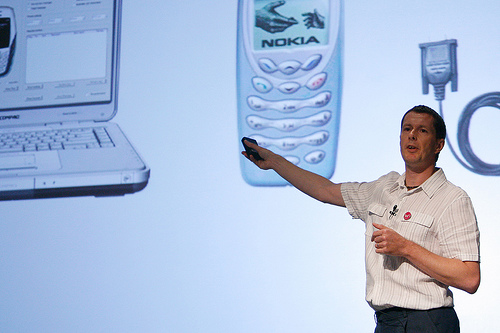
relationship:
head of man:
[392, 105, 452, 173] [244, 99, 487, 330]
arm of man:
[239, 134, 353, 216] [244, 99, 487, 330]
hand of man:
[369, 222, 405, 257] [244, 99, 487, 330]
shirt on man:
[338, 164, 481, 310] [244, 99, 487, 330]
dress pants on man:
[372, 301, 462, 331] [244, 99, 487, 330]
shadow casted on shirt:
[380, 253, 410, 271] [338, 164, 481, 310]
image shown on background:
[2, 1, 483, 330] [1, 1, 483, 329]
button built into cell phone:
[251, 74, 271, 93] [232, 0, 345, 190]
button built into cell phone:
[246, 93, 270, 112] [232, 0, 345, 190]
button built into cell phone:
[275, 80, 300, 94] [232, 0, 345, 190]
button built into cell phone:
[306, 110, 332, 126] [232, 0, 345, 190]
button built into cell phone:
[303, 129, 330, 147] [232, 0, 345, 190]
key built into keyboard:
[50, 140, 62, 146] [2, 123, 116, 153]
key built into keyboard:
[23, 146, 38, 152] [2, 123, 116, 153]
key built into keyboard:
[25, 136, 39, 142] [2, 123, 116, 153]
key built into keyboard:
[66, 127, 81, 133] [2, 123, 116, 153]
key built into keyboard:
[2, 137, 16, 144] [2, 123, 116, 153]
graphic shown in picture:
[0, 0, 157, 209] [2, 2, 484, 328]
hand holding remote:
[240, 137, 273, 172] [241, 135, 261, 159]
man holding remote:
[244, 99, 487, 330] [241, 135, 261, 159]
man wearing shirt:
[244, 99, 487, 330] [338, 164, 481, 310]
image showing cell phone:
[2, 1, 483, 330] [232, 0, 345, 190]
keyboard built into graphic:
[2, 123, 116, 153] [0, 0, 157, 209]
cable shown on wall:
[435, 89, 484, 179] [0, 5, 482, 331]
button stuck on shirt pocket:
[402, 210, 411, 218] [396, 208, 434, 241]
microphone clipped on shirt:
[386, 203, 398, 221] [338, 164, 481, 310]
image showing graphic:
[2, 1, 483, 330] [0, 0, 157, 209]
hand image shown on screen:
[254, 1, 298, 32] [252, 1, 332, 49]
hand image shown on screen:
[298, 7, 326, 30] [252, 1, 332, 49]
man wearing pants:
[244, 99, 487, 330] [371, 304, 462, 331]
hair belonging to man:
[398, 103, 448, 165] [244, 99, 487, 330]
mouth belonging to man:
[400, 140, 420, 154] [244, 99, 487, 330]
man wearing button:
[244, 99, 487, 330] [402, 210, 411, 218]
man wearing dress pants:
[244, 99, 487, 330] [372, 301, 462, 331]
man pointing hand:
[244, 99, 487, 330] [240, 137, 273, 172]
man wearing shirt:
[244, 99, 487, 330] [342, 169, 475, 313]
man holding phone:
[244, 99, 487, 330] [239, 135, 263, 163]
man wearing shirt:
[244, 99, 487, 330] [332, 160, 479, 303]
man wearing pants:
[244, 99, 487, 330] [370, 299, 461, 331]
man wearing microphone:
[244, 99, 487, 330] [386, 203, 398, 221]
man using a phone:
[244, 99, 487, 330] [239, 135, 263, 163]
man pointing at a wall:
[244, 99, 487, 330] [0, 5, 482, 331]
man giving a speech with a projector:
[244, 99, 487, 330] [224, 126, 266, 160]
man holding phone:
[244, 99, 487, 330] [232, 132, 267, 163]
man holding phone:
[244, 99, 487, 330] [240, 132, 270, 162]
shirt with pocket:
[338, 164, 481, 310] [358, 200, 433, 241]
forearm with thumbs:
[355, 179, 481, 296] [366, 217, 390, 227]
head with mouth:
[395, 104, 444, 173] [397, 139, 421, 160]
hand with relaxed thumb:
[361, 215, 414, 253] [362, 213, 392, 231]